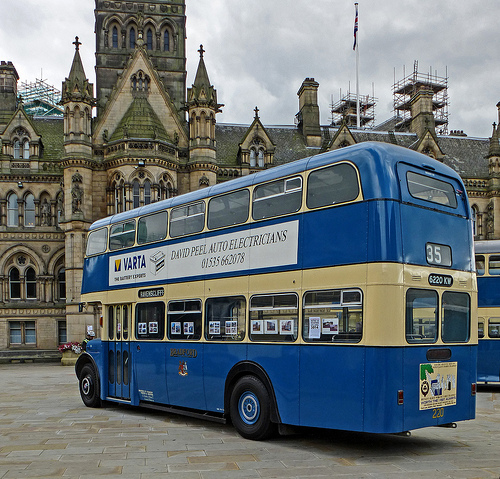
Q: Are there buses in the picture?
A: Yes, there is a bus.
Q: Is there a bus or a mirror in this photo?
A: Yes, there is a bus.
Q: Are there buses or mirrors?
A: Yes, there is a bus.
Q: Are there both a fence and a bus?
A: No, there is a bus but no fences.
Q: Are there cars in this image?
A: No, there are no cars.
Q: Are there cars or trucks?
A: No, there are no cars or trucks.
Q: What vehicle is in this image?
A: The vehicle is a bus.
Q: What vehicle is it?
A: The vehicle is a bus.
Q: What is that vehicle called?
A: That is a bus.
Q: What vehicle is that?
A: That is a bus.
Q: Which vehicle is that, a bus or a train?
A: That is a bus.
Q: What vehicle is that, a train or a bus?
A: That is a bus.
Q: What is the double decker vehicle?
A: The vehicle is a bus.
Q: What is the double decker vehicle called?
A: The vehicle is a bus.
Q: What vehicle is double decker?
A: The vehicle is a bus.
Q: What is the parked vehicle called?
A: The vehicle is a bus.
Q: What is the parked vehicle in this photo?
A: The vehicle is a bus.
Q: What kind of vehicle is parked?
A: The vehicle is a bus.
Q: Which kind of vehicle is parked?
A: The vehicle is a bus.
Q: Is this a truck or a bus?
A: This is a bus.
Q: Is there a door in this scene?
A: Yes, there is a door.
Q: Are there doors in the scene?
A: Yes, there is a door.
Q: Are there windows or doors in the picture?
A: Yes, there is a door.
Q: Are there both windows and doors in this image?
A: Yes, there are both a door and a window.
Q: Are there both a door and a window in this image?
A: Yes, there are both a door and a window.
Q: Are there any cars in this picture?
A: No, there are no cars.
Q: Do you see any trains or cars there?
A: No, there are no cars or trains.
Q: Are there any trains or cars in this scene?
A: No, there are no cars or trains.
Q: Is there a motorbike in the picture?
A: No, there are no motorcycles.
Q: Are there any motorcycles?
A: No, there are no motorcycles.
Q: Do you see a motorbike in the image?
A: No, there are no motorcycles.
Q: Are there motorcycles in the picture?
A: No, there are no motorcycles.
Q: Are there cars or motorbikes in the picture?
A: No, there are no motorbikes or cars.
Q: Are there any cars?
A: No, there are no cars.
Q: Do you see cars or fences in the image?
A: No, there are no cars or fences.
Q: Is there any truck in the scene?
A: No, there are no trucks.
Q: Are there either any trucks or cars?
A: No, there are no trucks or cars.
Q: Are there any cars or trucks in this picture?
A: No, there are no trucks or cars.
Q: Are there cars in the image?
A: No, there are no cars.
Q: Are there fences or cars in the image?
A: No, there are no cars or fences.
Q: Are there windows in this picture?
A: Yes, there is a window.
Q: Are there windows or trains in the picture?
A: Yes, there is a window.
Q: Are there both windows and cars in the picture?
A: No, there is a window but no cars.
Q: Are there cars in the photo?
A: No, there are no cars.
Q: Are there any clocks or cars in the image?
A: No, there are no cars or clocks.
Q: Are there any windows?
A: Yes, there is a window.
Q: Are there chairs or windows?
A: Yes, there is a window.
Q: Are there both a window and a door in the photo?
A: Yes, there are both a window and a door.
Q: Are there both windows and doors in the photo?
A: Yes, there are both a window and a door.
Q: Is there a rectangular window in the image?
A: Yes, there is a rectangular window.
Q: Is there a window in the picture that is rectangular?
A: Yes, there is a window that is rectangular.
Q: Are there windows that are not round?
A: Yes, there is a rectangular window.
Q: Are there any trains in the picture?
A: No, there are no trains.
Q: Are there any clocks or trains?
A: No, there are no trains or clocks.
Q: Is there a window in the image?
A: Yes, there is a window.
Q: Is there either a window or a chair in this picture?
A: Yes, there is a window.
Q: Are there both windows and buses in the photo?
A: Yes, there are both a window and a bus.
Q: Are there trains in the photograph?
A: No, there are no trains.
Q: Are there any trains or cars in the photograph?
A: No, there are no trains or cars.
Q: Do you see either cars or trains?
A: No, there are no trains or cars.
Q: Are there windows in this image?
A: Yes, there is a window.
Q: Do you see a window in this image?
A: Yes, there is a window.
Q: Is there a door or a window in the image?
A: Yes, there is a window.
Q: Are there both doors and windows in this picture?
A: Yes, there are both a window and a door.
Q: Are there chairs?
A: No, there are no chairs.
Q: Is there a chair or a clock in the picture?
A: No, there are no chairs or clocks.